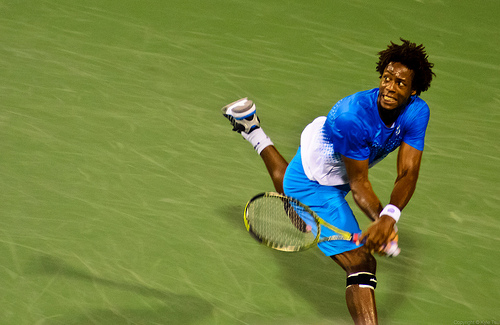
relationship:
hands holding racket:
[359, 215, 397, 253] [243, 180, 401, 263]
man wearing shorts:
[220, 38, 436, 325] [283, 146, 363, 256]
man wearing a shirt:
[220, 38, 436, 325] [284, 62, 451, 214]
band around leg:
[346, 270, 387, 288] [321, 230, 395, 322]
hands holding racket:
[361, 214, 397, 256] [243, 191, 400, 258]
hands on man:
[361, 214, 397, 256] [220, 44, 436, 323]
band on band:
[362, 197, 446, 235] [379, 204, 401, 223]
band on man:
[379, 204, 401, 223] [302, 51, 497, 305]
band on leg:
[346, 272, 378, 291] [330, 248, 379, 324]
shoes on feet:
[177, 62, 302, 179] [212, 75, 281, 147]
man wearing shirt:
[220, 44, 436, 323] [300, 87, 430, 187]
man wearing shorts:
[220, 38, 436, 325] [276, 147, 373, 252]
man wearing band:
[220, 44, 436, 323] [379, 204, 401, 223]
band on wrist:
[379, 204, 401, 223] [370, 203, 401, 229]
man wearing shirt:
[220, 44, 436, 323] [282, 80, 442, 195]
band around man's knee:
[346, 272, 378, 291] [337, 257, 379, 275]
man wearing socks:
[220, 38, 436, 325] [237, 127, 274, 156]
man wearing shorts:
[220, 44, 436, 323] [281, 144, 369, 258]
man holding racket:
[220, 38, 436, 325] [233, 165, 400, 272]